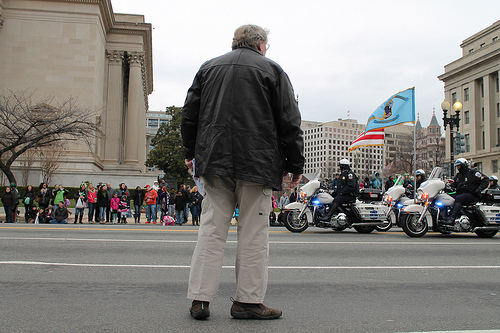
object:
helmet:
[452, 155, 470, 167]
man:
[316, 157, 359, 224]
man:
[176, 22, 307, 322]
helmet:
[335, 158, 350, 167]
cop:
[439, 157, 490, 228]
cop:
[405, 166, 425, 194]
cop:
[482, 174, 499, 194]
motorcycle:
[393, 166, 498, 238]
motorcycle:
[281, 166, 396, 233]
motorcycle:
[372, 174, 414, 231]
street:
[0, 224, 497, 332]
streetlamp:
[451, 99, 465, 115]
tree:
[0, 84, 106, 209]